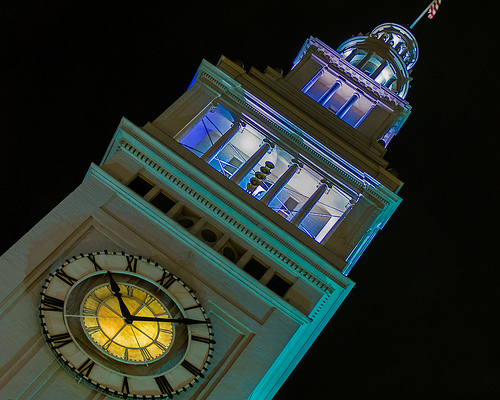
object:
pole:
[406, 1, 436, 32]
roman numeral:
[54, 268, 77, 287]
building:
[0, 0, 442, 397]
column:
[229, 140, 272, 184]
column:
[260, 156, 302, 206]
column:
[290, 179, 330, 225]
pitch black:
[0, 0, 496, 400]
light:
[335, 91, 361, 118]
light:
[316, 79, 342, 106]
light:
[308, 211, 339, 218]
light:
[246, 161, 274, 192]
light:
[201, 114, 214, 146]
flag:
[428, 0, 439, 19]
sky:
[417, 87, 484, 189]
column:
[198, 118, 243, 162]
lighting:
[173, 22, 416, 247]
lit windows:
[168, 96, 364, 243]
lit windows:
[300, 65, 377, 129]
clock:
[38, 249, 212, 399]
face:
[79, 282, 175, 361]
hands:
[107, 270, 212, 324]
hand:
[106, 270, 133, 324]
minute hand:
[127, 315, 212, 326]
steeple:
[333, 22, 420, 100]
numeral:
[190, 335, 217, 344]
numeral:
[155, 268, 175, 289]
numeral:
[76, 358, 97, 377]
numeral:
[47, 331, 73, 350]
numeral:
[55, 267, 78, 287]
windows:
[174, 101, 354, 243]